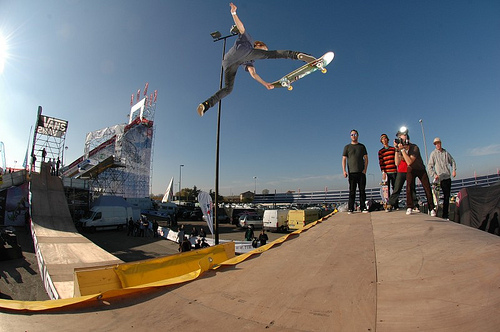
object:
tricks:
[196, 2, 335, 117]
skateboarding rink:
[0, 81, 158, 300]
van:
[262, 208, 289, 233]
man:
[196, 2, 316, 116]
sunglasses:
[350, 132, 358, 136]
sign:
[37, 115, 69, 135]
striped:
[378, 150, 394, 170]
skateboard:
[267, 51, 335, 91]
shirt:
[341, 142, 367, 173]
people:
[30, 153, 36, 171]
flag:
[197, 189, 214, 238]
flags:
[129, 94, 135, 107]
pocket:
[360, 172, 367, 176]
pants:
[347, 173, 365, 210]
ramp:
[29, 175, 127, 300]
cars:
[285, 208, 327, 229]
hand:
[361, 171, 366, 174]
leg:
[205, 69, 237, 103]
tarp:
[0, 207, 340, 313]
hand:
[263, 83, 275, 91]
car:
[237, 214, 263, 230]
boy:
[394, 128, 437, 216]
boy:
[376, 133, 401, 211]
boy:
[341, 129, 368, 215]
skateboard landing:
[0, 206, 499, 330]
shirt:
[377, 146, 398, 172]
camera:
[393, 137, 402, 145]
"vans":
[43, 116, 67, 131]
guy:
[425, 136, 456, 221]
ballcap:
[431, 137, 441, 145]